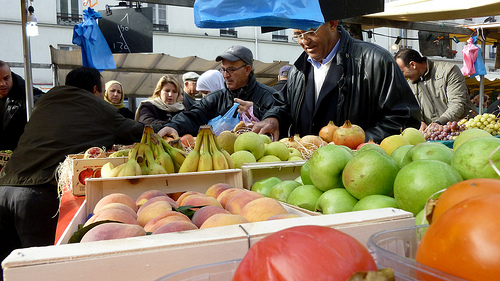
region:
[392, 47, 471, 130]
balding man in tan jacket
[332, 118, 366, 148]
onion in the front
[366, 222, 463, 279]
clear plastic basket with vegetables in it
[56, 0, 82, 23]
double pane window on the building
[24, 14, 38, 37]
light bulb on the pole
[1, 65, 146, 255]
guy reaching across the stand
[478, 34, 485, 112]
gray metal pole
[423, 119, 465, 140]
bunch of red grapes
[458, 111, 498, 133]
bunch of green grapes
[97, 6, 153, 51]
black poster with white lettering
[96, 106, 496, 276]
Lot of fruits kept in the shop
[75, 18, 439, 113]
Lot of peoples standing near the fruit shop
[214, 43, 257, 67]
A person wearing hat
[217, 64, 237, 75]
A person wearing specs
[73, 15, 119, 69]
Blue color plastic carry cover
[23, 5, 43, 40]
Light with holder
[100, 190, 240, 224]
A red apples kept in the box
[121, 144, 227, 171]
Banana kept in the box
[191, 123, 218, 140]
Stem of the banana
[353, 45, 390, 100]
A person wearing black color jacket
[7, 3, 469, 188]
several people at a produce stand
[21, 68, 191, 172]
a man selling produce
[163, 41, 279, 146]
a man buying produce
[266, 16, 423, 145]
a man buying produce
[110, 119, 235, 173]
several bunches of bananas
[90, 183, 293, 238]
a case of fresh peaches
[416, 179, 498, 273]
two fresh tomatoes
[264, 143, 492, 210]
a case of green apples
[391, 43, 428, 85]
the head of a man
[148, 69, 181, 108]
a woman with blonde hair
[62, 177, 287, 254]
peaches for sale at an outdoor market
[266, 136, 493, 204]
apples for sale at an outdoor market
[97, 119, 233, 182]
bananas for sale at an outdoor market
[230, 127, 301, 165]
apples for sale at an outdoor market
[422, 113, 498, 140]
grapes for sale at an outdoor market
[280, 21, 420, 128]
man in a black jacket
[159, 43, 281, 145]
man selecting fruit at an outdoor market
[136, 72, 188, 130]
woman wearing a scarf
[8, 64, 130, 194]
man in a dark jacket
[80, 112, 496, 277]
boxes of fruit for sale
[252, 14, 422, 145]
Man wearing a black jacket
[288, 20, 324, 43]
Glasses on man's face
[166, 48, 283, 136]
Man wearing a black jacket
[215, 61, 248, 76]
Glasses on man's face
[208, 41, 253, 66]
Hat on man's head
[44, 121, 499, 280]
Boxes of produce on table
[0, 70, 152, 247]
Man wearing a brown jacket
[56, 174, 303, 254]
Full box of peaches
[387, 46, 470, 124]
Man wearing a tan jacket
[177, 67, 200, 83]
Hat on a man's head